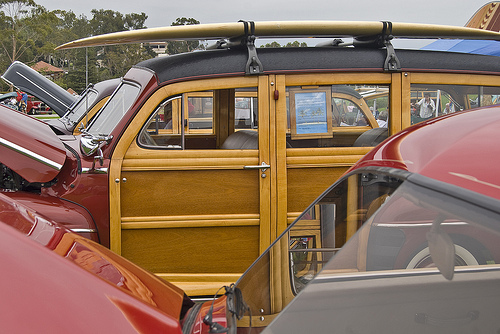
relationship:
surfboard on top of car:
[48, 17, 499, 58] [6, 43, 481, 292]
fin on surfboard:
[464, 8, 484, 27] [419, 4, 498, 56]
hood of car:
[52, 233, 189, 333] [9, 77, 237, 244]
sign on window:
[282, 83, 344, 153] [283, 90, 385, 142]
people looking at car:
[12, 85, 32, 112] [0, 19, 500, 296]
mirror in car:
[424, 208, 455, 279] [0, 103, 497, 332]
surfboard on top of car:
[48, 17, 498, 48] [6, 43, 481, 292]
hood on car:
[6, 111, 79, 191] [0, 38, 498, 313]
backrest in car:
[219, 130, 258, 152] [22, 24, 499, 319]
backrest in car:
[352, 126, 389, 145] [30, 28, 484, 298]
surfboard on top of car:
[239, 11, 376, 48] [68, 57, 342, 266]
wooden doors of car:
[111, 103, 279, 214] [6, 43, 481, 292]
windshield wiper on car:
[206, 282, 236, 330] [0, 103, 497, 332]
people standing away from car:
[20, 90, 27, 112] [14, 17, 337, 269]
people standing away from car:
[20, 90, 27, 112] [36, 63, 108, 123]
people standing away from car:
[20, 90, 27, 112] [13, 87, 43, 112]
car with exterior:
[0, 19, 500, 296] [95, 78, 484, 282]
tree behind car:
[0, 0, 80, 95] [61, 37, 339, 263]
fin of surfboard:
[464, 0, 500, 32] [56, 14, 498, 49]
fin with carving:
[464, 0, 500, 32] [453, 0, 498, 33]